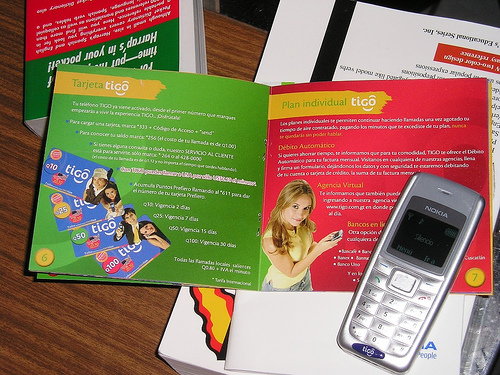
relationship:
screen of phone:
[391, 207, 463, 265] [332, 169, 486, 373]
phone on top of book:
[336, 171, 488, 374] [77, 69, 340, 291]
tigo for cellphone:
[39, 61, 482, 291] [336, 172, 486, 374]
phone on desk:
[332, 169, 486, 373] [4, 24, 496, 374]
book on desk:
[25, 73, 493, 293] [10, 290, 151, 364]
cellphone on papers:
[332, 147, 438, 322] [234, 75, 354, 153]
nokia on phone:
[420, 195, 443, 220] [332, 169, 486, 373]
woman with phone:
[260, 179, 344, 289] [331, 232, 341, 239]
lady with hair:
[259, 168, 334, 290] [257, 167, 315, 249]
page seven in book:
[256, 76, 495, 294] [29, 63, 494, 293]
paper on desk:
[26, 60, 368, 295] [4, 24, 496, 374]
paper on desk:
[352, 77, 493, 173] [4, 24, 496, 374]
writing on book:
[141, 201, 236, 249] [25, 73, 493, 293]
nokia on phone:
[424, 204, 449, 220] [332, 169, 486, 373]